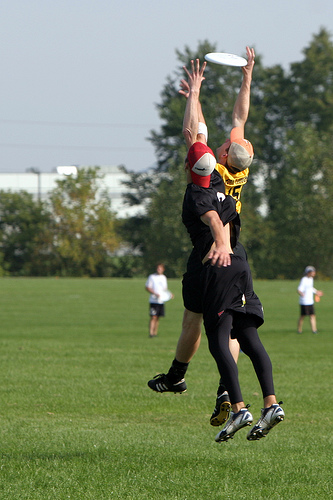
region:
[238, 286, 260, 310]
part of a sweater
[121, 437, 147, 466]
part of a fiedl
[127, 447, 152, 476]
part of a grass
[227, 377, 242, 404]
[art of a leg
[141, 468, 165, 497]
part of a grass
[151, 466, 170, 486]
part of a ground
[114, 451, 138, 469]
part of a ground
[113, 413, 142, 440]
part of a ground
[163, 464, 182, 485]
part of a ground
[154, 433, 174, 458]
part of a ground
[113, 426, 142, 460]
part of a ground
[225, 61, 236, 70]
edge of a dish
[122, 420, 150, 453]
part of a ground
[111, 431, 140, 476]
part of a grass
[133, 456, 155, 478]
part of a grass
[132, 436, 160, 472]
part of a ground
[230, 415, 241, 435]
part of as shoe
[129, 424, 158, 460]
part of a ground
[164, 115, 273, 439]
these are two boys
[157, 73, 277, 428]
they are on air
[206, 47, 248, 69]
this is a frisbee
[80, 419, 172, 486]
this is the grass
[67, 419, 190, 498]
the grass is green in color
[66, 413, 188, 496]
the grass is short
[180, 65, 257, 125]
the hands are above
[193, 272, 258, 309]
these are the shorts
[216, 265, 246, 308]
the shorts are black in color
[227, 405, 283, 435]
this is a pair of boots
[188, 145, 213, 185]
the person is wearing a hat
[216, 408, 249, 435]
the cleats the man is wearing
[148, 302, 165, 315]
black shorts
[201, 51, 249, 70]
white frisbee in the air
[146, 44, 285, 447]
two men jumping for a frisbee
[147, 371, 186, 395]
black Adidas cleats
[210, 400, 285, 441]
pair of black and white shoes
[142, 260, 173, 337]
man holding a white frisbee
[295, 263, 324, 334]
man wearing a white shirt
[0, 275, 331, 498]
field of green grass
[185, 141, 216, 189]
red and white baseball cap